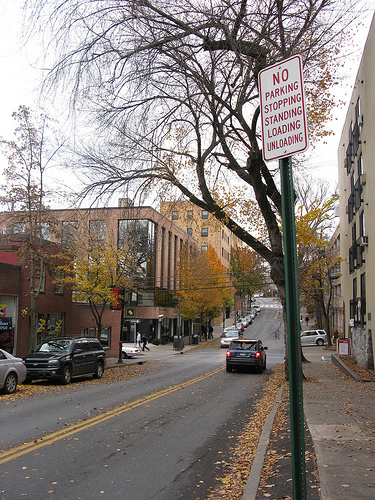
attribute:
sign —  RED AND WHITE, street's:
[257, 53, 308, 161]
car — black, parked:
[26, 337, 107, 381]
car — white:
[300, 328, 327, 347]